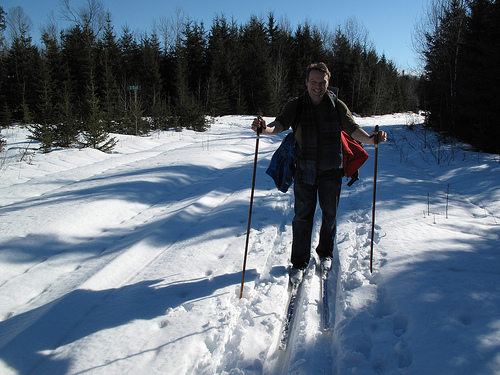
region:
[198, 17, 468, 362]
a man skiing in the snow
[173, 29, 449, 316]
a man in the snow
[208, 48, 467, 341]
a man skiing during the day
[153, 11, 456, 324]
a man in snow during the day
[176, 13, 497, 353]
a person on skies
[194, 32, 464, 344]
a person holding ski poles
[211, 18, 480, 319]
a man smiling while skiing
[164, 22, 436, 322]
a man during the day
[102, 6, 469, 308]
snow covering the ground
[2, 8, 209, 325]
Snowy landscape with green trees.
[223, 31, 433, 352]
White man wearing skis and using poles.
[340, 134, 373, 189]
Bright red back pack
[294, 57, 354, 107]
White man with big grin.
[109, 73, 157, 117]
Green and white street sign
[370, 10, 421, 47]
Blue sky with no clouds.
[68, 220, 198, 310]
Fluffy white snow on ground.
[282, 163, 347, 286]
Men's straight leg bluejeans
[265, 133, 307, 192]
Blue men's jacket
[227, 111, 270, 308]
Ski pole being used on snowy ground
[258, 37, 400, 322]
man standing in snow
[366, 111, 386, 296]
left ski pole in hand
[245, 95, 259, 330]
right ski pole in hand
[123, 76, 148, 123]
road sign in background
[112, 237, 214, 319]
white snow on ground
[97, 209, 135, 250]
tracks in the snow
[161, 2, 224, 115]
evergreen trees in the background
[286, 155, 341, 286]
black ski pants on person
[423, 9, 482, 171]
group of evergreen trees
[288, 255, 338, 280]
white ski boots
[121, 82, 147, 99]
A number sign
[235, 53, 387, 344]
A man skiing on a road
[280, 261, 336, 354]
Two snow skis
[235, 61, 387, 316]
A man holding two ski poles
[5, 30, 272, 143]
A row of trees along a snowy road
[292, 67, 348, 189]
A scarf around a man's neck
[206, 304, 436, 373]
Tracks in the snow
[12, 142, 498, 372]
A snow covered road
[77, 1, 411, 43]
A clear blue sky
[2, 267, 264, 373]
A skier's shadow on the snow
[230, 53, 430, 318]
Skier holding ski poles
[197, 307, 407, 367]
Tracks in the snow from skis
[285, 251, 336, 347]
Skis on skiers feet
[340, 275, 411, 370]
Marks in the snow from ski poles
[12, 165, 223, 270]
Shadows on the snow from trees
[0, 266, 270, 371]
Shadow in the snow of skier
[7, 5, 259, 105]
Trees behind the ski trail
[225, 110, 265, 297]
Ski pole in skiers hand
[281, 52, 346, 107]
Smiling skier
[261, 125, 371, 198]
Things skier is carrying